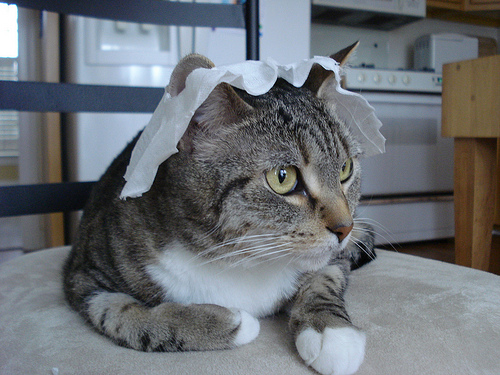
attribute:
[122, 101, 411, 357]
cat — gray, laying, silver, sitting, close, resting, looking, watching, small, black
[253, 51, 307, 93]
tissue — white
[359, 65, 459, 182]
oven — white, behind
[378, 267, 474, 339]
seat — brown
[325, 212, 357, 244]
nose — pink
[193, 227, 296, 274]
whiskers — white